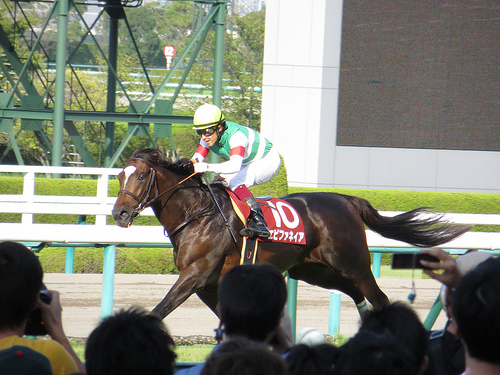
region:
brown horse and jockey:
[98, 85, 406, 320]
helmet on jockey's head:
[186, 103, 232, 125]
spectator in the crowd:
[220, 265, 287, 339]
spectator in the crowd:
[211, 342, 284, 373]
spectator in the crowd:
[346, 328, 405, 364]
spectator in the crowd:
[291, 343, 338, 367]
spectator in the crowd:
[91, 311, 179, 371]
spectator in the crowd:
[4, 245, 74, 366]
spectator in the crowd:
[457, 274, 499, 369]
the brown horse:
[93, 133, 440, 315]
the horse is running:
[69, 141, 469, 319]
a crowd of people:
[10, 247, 497, 359]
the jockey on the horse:
[178, 103, 303, 226]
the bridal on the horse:
[112, 169, 215, 206]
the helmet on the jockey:
[168, 104, 228, 123]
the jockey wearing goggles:
[189, 118, 244, 153]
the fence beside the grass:
[4, 170, 136, 237]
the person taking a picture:
[354, 220, 498, 359]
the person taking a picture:
[6, 243, 68, 323]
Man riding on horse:
[87, 62, 429, 322]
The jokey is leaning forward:
[180, 102, 313, 239]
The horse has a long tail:
[345, 181, 469, 258]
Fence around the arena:
[19, 133, 144, 287]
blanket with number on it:
[226, 193, 322, 259]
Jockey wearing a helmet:
[198, 103, 220, 125]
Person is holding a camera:
[387, 240, 477, 323]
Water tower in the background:
[9, 27, 174, 179]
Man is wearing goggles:
[192, 127, 245, 161]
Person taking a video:
[3, 243, 83, 369]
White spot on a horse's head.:
[112, 150, 160, 203]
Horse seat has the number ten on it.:
[254, 194, 315, 264]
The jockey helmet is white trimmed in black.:
[184, 86, 261, 161]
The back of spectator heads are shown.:
[1, 244, 489, 373]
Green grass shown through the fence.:
[6, 159, 498, 279]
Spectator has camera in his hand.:
[382, 234, 475, 305]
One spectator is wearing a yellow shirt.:
[1, 315, 114, 372]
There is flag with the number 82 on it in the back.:
[139, 38, 214, 89]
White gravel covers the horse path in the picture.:
[30, 269, 497, 347]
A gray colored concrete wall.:
[340, 6, 498, 156]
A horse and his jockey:
[91, 62, 415, 323]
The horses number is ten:
[226, 187, 324, 285]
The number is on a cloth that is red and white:
[214, 197, 325, 266]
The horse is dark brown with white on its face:
[108, 149, 245, 272]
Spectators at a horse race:
[4, 224, 484, 369]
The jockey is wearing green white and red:
[191, 131, 295, 198]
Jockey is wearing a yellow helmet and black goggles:
[182, 106, 233, 148]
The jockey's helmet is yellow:
[193, 109, 226, 151]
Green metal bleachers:
[6, 9, 174, 143]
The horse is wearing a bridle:
[106, 154, 218, 248]